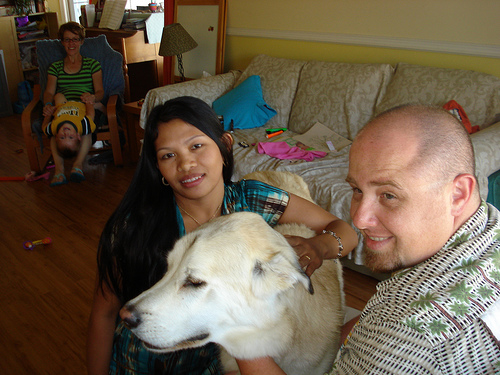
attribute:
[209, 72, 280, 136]
pillow — blue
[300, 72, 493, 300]
man — bald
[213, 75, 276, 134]
pillow — Blue 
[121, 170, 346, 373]
dog — large, white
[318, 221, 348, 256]
bracelet — silver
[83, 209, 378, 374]
dog — white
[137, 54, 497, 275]
sofa — White 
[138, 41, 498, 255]
sofa — gold , white 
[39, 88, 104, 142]
shirt — black, yellow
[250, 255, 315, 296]
ears — white 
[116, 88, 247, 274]
hair — dark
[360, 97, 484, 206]
hair — little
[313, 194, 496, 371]
shirt — white , green 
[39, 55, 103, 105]
shirt — green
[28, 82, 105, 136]
lap — her